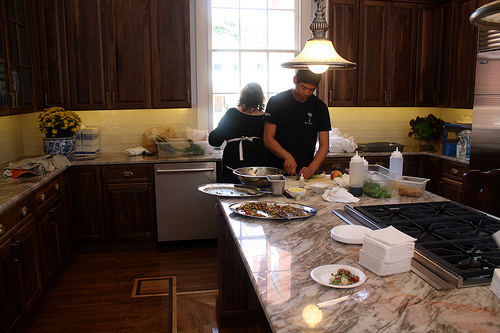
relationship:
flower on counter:
[36, 107, 88, 133] [3, 150, 184, 166]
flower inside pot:
[36, 107, 88, 133] [41, 139, 75, 159]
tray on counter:
[242, 199, 315, 225] [220, 171, 444, 322]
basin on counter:
[231, 164, 284, 186] [3, 150, 184, 166]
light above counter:
[294, 37, 346, 73] [220, 171, 444, 322]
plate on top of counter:
[313, 258, 359, 292] [220, 171, 444, 322]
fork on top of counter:
[322, 287, 369, 308] [220, 171, 444, 322]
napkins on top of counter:
[361, 212, 409, 281] [220, 171, 444, 322]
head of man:
[293, 66, 320, 94] [267, 69, 329, 174]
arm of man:
[261, 92, 299, 176] [267, 69, 329, 174]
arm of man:
[305, 114, 334, 174] [267, 69, 329, 174]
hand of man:
[283, 154, 293, 171] [267, 69, 329, 174]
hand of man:
[300, 166, 313, 179] [267, 69, 329, 174]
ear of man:
[292, 75, 304, 87] [267, 69, 329, 174]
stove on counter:
[369, 199, 499, 282] [220, 171, 444, 322]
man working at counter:
[267, 69, 329, 174] [220, 171, 444, 322]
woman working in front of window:
[208, 86, 279, 181] [208, 3, 298, 123]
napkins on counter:
[361, 212, 409, 281] [220, 171, 444, 322]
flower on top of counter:
[36, 107, 88, 133] [3, 150, 184, 166]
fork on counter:
[322, 287, 369, 308] [220, 171, 444, 322]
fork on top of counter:
[322, 287, 369, 308] [3, 150, 184, 166]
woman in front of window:
[208, 86, 279, 181] [208, 3, 298, 123]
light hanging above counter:
[294, 37, 346, 73] [220, 171, 444, 322]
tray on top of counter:
[242, 199, 315, 225] [220, 171, 444, 322]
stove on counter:
[369, 199, 499, 282] [3, 150, 184, 166]